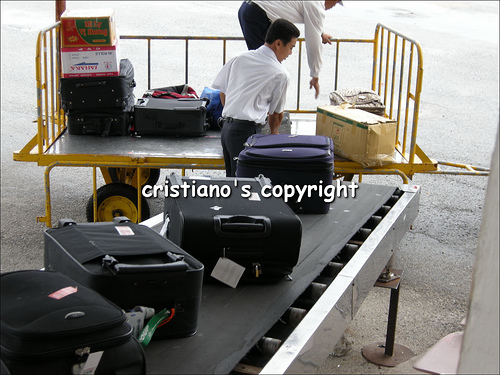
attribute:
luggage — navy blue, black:
[167, 135, 338, 279]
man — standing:
[219, 21, 299, 145]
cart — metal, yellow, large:
[16, 16, 447, 182]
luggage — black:
[67, 75, 205, 144]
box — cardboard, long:
[315, 100, 396, 163]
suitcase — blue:
[239, 132, 338, 206]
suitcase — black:
[159, 170, 302, 286]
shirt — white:
[218, 45, 280, 116]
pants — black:
[221, 121, 251, 178]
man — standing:
[240, 0, 335, 57]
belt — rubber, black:
[306, 180, 386, 261]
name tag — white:
[208, 254, 253, 294]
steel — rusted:
[366, 269, 413, 368]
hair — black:
[266, 15, 302, 50]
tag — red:
[48, 285, 79, 303]